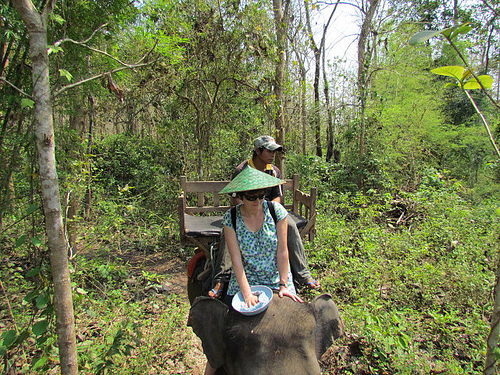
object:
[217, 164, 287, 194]
hat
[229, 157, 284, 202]
yellow shirt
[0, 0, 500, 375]
green vegetation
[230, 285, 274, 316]
bowl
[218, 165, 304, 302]
lady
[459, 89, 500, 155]
branch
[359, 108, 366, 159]
branch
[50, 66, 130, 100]
branch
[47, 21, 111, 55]
branch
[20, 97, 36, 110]
leaf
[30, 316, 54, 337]
leaf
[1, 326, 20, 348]
leaf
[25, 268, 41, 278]
leaf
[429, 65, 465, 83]
green leaf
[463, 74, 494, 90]
green leaf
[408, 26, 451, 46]
green leaf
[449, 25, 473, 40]
green leaf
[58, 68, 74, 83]
green leaf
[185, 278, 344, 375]
elephant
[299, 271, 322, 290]
left foot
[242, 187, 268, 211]
head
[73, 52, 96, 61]
woods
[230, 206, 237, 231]
strap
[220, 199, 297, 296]
shirt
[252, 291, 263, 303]
handle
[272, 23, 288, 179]
trunk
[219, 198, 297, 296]
blue top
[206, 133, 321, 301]
man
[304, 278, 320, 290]
slippers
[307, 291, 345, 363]
ear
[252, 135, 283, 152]
hat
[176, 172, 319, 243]
seat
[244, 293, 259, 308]
hand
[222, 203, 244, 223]
shoulder